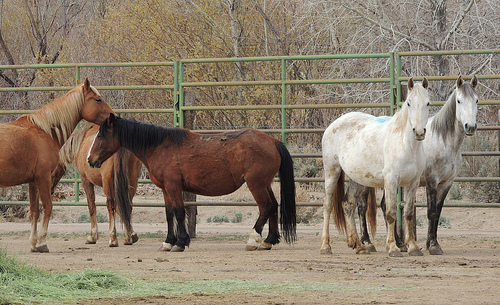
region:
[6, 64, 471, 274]
the horses are standing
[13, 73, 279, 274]
horses are brown in color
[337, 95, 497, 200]
horses are brown in color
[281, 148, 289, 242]
the tail is black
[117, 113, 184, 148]
the bak is black in color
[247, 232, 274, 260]
hoofs are white in color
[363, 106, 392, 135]
horse has a blue mark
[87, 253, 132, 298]
grasses are on ground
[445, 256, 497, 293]
the floor is sandy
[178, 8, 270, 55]
the treee branches are dried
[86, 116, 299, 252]
red horse with black mane and tail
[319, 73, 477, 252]
two white horses looking at camera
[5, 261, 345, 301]
hay scattered on the ground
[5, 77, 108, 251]
red horse with a yellow mane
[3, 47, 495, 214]
green panels of corral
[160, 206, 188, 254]
horse's legs with hooves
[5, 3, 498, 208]
trees behind the corral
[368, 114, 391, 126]
blue mark on back of white horse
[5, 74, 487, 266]
horses standing in a corral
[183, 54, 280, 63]
green metal fence pole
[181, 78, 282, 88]
green metal fence pole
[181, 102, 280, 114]
green metal fence pole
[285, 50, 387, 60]
green metal fence pole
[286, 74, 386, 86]
green metal fence pole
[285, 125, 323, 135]
green metal fence pole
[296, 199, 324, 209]
green metal fence pole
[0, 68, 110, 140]
this is a horse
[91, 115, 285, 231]
`this is a horse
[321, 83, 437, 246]
this is a horse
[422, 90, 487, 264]
this is a horse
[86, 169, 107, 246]
the leg of a horse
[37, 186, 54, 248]
the leg of a horse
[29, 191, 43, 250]
the leg of a horse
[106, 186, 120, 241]
the leg of a horse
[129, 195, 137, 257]
the leg of a horse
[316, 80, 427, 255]
white horse on ground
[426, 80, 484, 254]
white and grey horse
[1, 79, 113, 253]
brown and tan horse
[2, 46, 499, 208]
green metal barrier fence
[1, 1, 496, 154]
trees with no leaves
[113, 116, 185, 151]
black mane on horse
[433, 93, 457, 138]
grey mane on horse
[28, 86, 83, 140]
blond mane on horse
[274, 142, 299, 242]
black tail on horse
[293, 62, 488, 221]
white horses on the dirt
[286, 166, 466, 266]
legs of the animals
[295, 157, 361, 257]
back leg of the horse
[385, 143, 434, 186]
front of the animal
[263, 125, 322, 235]
black tail of the horse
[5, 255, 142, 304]
hay on the ground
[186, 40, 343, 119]
poles next to the horse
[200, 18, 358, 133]
green fence near horses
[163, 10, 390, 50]
many branches on the trees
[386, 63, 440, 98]
ears on the horse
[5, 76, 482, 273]
Horses in a group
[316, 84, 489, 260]
Horses in a group